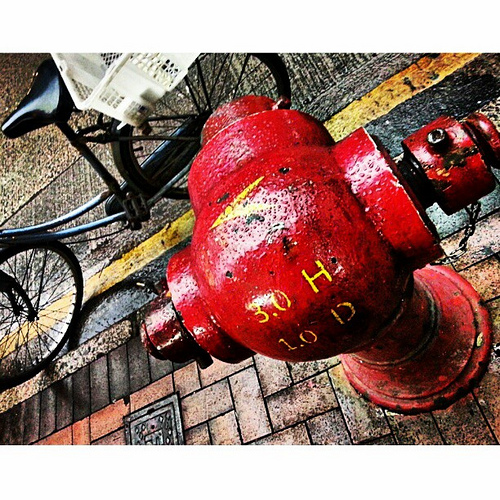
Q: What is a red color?
A: A fire hydrant.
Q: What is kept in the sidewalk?
A: A fire hydrant.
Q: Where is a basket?
A: In the cycle.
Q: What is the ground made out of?
A: Bricks.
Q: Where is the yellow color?
A: On the road.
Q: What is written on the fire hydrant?
A: Some numbers.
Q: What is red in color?
A: A fire hydrant.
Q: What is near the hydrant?
A: A bike.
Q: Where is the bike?
A: On the road.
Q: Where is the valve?
A: On the fire hydrant.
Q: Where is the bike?
A: Near the hydrant.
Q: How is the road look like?
A: Wet.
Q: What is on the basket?
A: White plastic basket.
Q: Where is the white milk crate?
A: On the back of the bike.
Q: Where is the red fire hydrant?
A: On the sidewalk.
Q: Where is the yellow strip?
A: On the side of the road.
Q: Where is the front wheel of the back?
A: On the front of the bike.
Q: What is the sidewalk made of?
A: Bricks.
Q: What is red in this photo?
A: A fire hydrant.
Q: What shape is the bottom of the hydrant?
A: A circle.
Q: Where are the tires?
A: On the bike.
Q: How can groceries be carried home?
A: In the basket.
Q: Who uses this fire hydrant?
A: Firemen.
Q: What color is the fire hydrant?
A: Red.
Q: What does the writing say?
A: 3.0 H 1.0 D.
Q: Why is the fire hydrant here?
A: To aid is extinguishing fires.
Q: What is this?
A: A fire hydrant.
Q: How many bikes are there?
A: One.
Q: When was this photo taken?
A: During the day.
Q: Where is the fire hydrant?
A: In on a sidewalk.